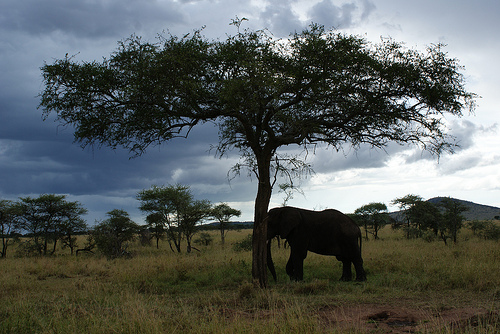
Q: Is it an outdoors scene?
A: Yes, it is outdoors.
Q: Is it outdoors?
A: Yes, it is outdoors.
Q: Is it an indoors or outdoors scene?
A: It is outdoors.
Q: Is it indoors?
A: No, it is outdoors.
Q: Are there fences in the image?
A: No, there are no fences.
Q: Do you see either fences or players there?
A: No, there are no fences or players.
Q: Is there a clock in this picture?
A: No, there are no clocks.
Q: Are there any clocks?
A: No, there are no clocks.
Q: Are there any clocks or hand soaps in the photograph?
A: No, there are no clocks or hand soaps.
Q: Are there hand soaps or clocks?
A: No, there are no clocks or hand soaps.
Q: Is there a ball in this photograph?
A: No, there are no balls.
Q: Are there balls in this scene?
A: No, there are no balls.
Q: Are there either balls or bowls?
A: No, there are no balls or bowls.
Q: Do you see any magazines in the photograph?
A: No, there are no magazines.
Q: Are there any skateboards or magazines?
A: No, there are no magazines or skateboards.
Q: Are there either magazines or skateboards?
A: No, there are no magazines or skateboards.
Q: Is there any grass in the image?
A: Yes, there is grass.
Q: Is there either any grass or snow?
A: Yes, there is grass.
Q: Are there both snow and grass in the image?
A: No, there is grass but no snow.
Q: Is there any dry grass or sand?
A: Yes, there is dry grass.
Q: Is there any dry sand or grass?
A: Yes, there is dry grass.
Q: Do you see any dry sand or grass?
A: Yes, there is dry grass.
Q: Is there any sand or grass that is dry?
A: Yes, the grass is dry.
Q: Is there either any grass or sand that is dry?
A: Yes, the grass is dry.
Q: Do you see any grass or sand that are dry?
A: Yes, the grass is dry.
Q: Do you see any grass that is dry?
A: Yes, there is dry grass.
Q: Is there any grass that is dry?
A: Yes, there is grass that is dry.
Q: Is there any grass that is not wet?
A: Yes, there is dry grass.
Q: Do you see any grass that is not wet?
A: Yes, there is dry grass.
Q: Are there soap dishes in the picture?
A: No, there are no soap dishes.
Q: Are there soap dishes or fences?
A: No, there are no soap dishes or fences.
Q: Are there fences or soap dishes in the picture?
A: No, there are no soap dishes or fences.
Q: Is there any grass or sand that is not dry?
A: No, there is grass but it is dry.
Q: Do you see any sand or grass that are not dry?
A: No, there is grass but it is dry.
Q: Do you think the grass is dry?
A: Yes, the grass is dry.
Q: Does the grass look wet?
A: No, the grass is dry.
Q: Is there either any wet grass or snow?
A: No, there is grass but it is dry.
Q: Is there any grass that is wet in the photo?
A: No, there is grass but it is dry.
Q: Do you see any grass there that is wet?
A: No, there is grass but it is dry.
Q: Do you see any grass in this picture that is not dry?
A: No, there is grass but it is dry.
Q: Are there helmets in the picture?
A: No, there are no helmets.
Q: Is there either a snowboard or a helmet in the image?
A: No, there are no helmets or snowboards.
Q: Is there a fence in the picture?
A: No, there are no fences.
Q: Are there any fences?
A: No, there are no fences.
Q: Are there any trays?
A: No, there are no trays.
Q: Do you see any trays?
A: No, there are no trays.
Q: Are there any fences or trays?
A: No, there are no trays or fences.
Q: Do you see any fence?
A: No, there are no fences.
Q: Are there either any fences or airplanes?
A: No, there are no fences or airplanes.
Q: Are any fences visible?
A: No, there are no fences.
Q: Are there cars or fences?
A: No, there are no fences or cars.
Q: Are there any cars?
A: No, there are no cars.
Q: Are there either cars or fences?
A: No, there are no cars or fences.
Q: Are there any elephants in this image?
A: Yes, there is an elephant.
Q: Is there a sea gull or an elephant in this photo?
A: Yes, there is an elephant.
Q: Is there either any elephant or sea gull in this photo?
A: Yes, there is an elephant.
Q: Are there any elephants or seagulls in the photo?
A: Yes, there is an elephant.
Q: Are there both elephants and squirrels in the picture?
A: No, there is an elephant but no squirrels.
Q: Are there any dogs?
A: No, there are no dogs.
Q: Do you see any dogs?
A: No, there are no dogs.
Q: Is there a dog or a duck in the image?
A: No, there are no dogs or ducks.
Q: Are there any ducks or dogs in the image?
A: No, there are no dogs or ducks.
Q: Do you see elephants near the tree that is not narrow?
A: Yes, there is an elephant near the tree.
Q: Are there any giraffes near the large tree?
A: No, there is an elephant near the tree.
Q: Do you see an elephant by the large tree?
A: Yes, there is an elephant by the tree.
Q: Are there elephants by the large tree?
A: Yes, there is an elephant by the tree.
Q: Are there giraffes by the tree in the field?
A: No, there is an elephant by the tree.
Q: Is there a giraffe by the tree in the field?
A: No, there is an elephant by the tree.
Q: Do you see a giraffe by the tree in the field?
A: No, there is an elephant by the tree.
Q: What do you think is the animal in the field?
A: The animal is an elephant.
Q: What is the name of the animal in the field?
A: The animal is an elephant.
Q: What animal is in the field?
A: The animal is an elephant.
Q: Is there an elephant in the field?
A: Yes, there is an elephant in the field.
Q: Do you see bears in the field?
A: No, there is an elephant in the field.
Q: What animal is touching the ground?
A: The elephant is touching the ground.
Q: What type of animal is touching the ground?
A: The animal is an elephant.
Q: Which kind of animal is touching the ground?
A: The animal is an elephant.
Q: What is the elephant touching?
A: The elephant is touching the ground.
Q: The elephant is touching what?
A: The elephant is touching the ground.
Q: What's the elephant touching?
A: The elephant is touching the ground.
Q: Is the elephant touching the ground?
A: Yes, the elephant is touching the ground.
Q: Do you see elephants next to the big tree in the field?
A: Yes, there is an elephant next to the tree.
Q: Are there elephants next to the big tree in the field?
A: Yes, there is an elephant next to the tree.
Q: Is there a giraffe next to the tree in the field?
A: No, there is an elephant next to the tree.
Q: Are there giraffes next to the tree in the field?
A: No, there is an elephant next to the tree.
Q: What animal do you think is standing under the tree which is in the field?
A: The elephant is standing under the tree.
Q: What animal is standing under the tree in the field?
A: The animal is an elephant.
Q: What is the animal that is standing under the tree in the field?
A: The animal is an elephant.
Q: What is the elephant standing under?
A: The elephant is standing under the tree.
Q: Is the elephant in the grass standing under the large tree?
A: Yes, the elephant is standing under the tree.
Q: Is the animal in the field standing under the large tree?
A: Yes, the elephant is standing under the tree.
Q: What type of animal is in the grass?
A: The animal is an elephant.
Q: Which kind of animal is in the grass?
A: The animal is an elephant.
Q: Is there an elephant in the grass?
A: Yes, there is an elephant in the grass.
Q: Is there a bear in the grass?
A: No, there is an elephant in the grass.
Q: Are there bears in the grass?
A: No, there is an elephant in the grass.